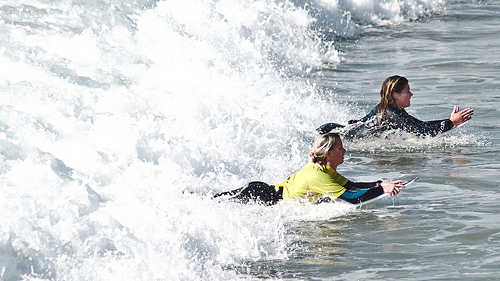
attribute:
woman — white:
[208, 133, 408, 207]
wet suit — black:
[317, 98, 455, 142]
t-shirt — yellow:
[275, 160, 347, 204]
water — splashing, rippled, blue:
[0, 5, 499, 279]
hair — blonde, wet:
[312, 130, 337, 169]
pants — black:
[212, 180, 284, 206]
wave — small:
[3, 3, 448, 280]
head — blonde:
[307, 133, 347, 169]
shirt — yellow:
[276, 162, 347, 202]